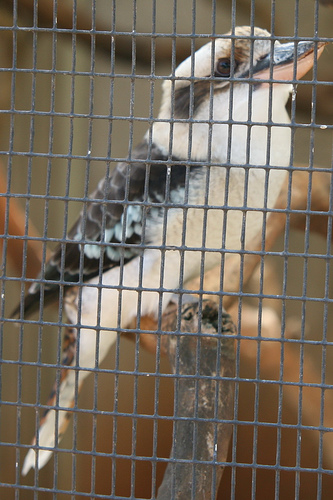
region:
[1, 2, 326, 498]
Metal mesh of bird cage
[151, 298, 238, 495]
Wooden perch for bird to stand on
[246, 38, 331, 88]
Black and pink beak of bird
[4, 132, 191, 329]
Dark feathered wing of bird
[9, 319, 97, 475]
Tail of bird with white underneath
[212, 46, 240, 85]
Brown eye of bird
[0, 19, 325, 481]
Small white, brown and black bird on perch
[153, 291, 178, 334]
Pink leg of bird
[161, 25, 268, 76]
Light brown crown area of bird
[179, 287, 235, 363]
Knot area of wooden perch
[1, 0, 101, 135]
black bird cage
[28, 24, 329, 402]
white and black bird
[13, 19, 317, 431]
bird perching on tree limb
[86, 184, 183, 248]
gray colored feathers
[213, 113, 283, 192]
white colored feathers on bird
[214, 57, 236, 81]
brown birds eye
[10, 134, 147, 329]
wing of a bird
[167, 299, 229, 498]
part of a tree branch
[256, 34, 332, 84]
birds beak that is two toned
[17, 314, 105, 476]
tail feathers of a bird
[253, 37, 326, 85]
Bird's black and white beak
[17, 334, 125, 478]
Bird's white, brown, and black tail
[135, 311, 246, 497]
Branch the bird is perched on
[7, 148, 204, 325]
White and dark brown bird wings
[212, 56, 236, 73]
Bird's brown eye with black pupil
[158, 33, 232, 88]
White top of bird's head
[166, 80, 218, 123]
Brown stripe on bird's face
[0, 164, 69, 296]
Blurred brown branch in the background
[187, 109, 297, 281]
Bird's white chest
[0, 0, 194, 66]
Blurred brown branch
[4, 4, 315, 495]
small bird in cage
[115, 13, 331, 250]
bird with black and orange beak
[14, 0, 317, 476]
bird looking at camera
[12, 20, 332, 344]
bird looking up in cage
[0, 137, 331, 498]
tree branch in birdcage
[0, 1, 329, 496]
metal caging surrounding bird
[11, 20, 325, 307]
bird with white belly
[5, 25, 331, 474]
brown stripe on bird's face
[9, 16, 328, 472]
tip of bird tail with white feathers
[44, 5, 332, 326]
claws wrapped around branch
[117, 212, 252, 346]
Bird standing on a branch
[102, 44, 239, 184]
bird with white and gray feathers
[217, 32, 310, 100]
Bird with brown eyes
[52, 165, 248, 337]
Bird behind metal wire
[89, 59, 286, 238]
Bird behind metal wire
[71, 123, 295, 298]
Bird behind metal wire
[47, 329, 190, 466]
Bird behind metal wire